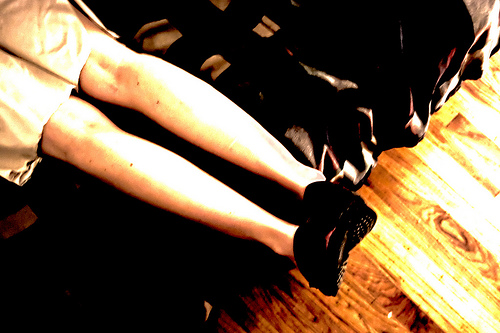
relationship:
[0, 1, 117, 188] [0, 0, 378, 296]
short on boy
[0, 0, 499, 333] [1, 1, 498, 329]
blanket on bed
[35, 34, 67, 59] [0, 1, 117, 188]
wrinkles on short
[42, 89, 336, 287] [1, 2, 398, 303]
leg on boy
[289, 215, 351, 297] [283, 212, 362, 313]
foot on foot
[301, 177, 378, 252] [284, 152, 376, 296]
foot on feet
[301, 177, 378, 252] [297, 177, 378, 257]
foot on foot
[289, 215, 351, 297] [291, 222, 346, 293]
foot on foot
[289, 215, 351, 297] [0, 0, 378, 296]
foot on boy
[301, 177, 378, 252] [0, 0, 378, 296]
foot on boy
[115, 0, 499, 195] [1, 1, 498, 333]
blanket on bed